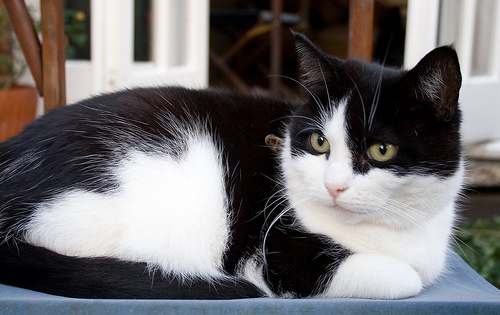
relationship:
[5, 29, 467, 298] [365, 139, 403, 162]
cat has eye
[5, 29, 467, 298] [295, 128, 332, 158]
cat has eye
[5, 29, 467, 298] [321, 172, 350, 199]
cat has nose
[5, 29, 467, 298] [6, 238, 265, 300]
cat has tail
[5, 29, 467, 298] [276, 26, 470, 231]
cat has face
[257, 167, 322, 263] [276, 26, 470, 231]
whiskers on face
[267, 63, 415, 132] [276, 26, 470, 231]
whiskers on face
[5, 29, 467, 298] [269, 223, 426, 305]
cat has paw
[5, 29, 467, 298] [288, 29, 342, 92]
cat has ear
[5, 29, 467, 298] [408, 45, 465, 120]
cat has ear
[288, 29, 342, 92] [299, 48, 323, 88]
ear has hairs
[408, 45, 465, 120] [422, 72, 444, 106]
ear has hairs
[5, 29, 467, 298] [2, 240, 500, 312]
cat resting on chair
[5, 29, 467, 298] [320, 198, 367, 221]
cat has mouth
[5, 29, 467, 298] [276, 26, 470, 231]
cat has head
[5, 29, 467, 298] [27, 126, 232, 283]
cat has hair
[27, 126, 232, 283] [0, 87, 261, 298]
hair on hind quarters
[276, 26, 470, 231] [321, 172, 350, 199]
face has nose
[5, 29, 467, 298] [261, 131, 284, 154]
cat has collar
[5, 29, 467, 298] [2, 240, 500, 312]
cat on chair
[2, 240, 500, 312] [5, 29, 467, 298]
blanket underneath cat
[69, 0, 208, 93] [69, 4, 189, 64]
door has window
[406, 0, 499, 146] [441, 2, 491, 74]
door has window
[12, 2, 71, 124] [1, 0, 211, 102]
beam front of wall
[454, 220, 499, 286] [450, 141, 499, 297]
foilag on ground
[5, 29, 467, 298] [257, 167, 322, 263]
cat has whiskers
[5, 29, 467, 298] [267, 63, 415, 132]
cat has whiskers